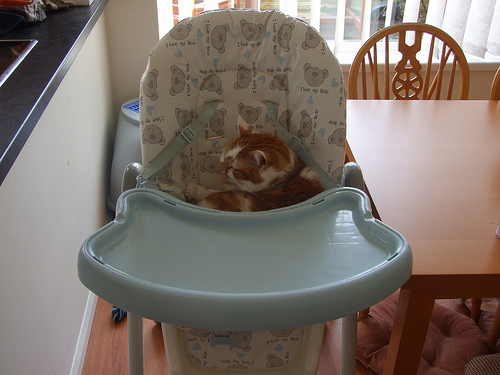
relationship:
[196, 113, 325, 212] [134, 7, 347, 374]
animal in car seat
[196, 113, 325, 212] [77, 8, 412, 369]
animal in highchair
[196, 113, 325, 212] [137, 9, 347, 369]
animal resting against cushion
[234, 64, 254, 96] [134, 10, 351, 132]
print on chair cushion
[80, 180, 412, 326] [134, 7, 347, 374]
tray at car seat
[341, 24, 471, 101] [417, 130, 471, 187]
chair at table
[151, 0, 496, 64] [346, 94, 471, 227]
blinds behind table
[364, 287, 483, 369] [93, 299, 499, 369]
cushion on floor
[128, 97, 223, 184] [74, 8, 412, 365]
strap on chair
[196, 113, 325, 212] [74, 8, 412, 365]
animal in chair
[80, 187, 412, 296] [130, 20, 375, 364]
tray on chair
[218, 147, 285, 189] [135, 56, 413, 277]
stripe on cat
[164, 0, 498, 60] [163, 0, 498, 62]
blinds at windows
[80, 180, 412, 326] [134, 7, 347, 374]
tray of car seat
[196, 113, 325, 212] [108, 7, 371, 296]
animal in car seat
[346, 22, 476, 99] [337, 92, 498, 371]
chair at table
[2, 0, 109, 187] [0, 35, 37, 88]
counter with sink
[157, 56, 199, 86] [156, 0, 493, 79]
slats on window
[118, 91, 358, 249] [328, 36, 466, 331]
animal in chair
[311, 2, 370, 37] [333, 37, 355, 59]
blinds on window sill